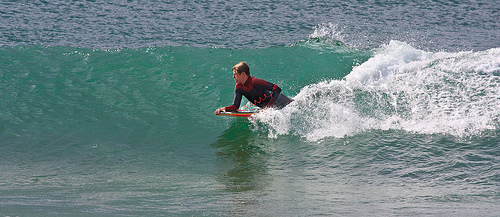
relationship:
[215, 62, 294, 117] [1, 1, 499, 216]
surfer in water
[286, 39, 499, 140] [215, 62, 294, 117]
splashing behind surfer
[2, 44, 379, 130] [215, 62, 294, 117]
wave near surfer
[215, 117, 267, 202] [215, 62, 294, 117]
shadow under surfer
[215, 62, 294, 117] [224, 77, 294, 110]
surfer in suit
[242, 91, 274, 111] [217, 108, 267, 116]
cable on surfboard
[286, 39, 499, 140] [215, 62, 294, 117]
splashing near surfer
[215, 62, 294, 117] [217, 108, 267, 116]
surfer on surfboard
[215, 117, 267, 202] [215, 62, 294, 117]
shadow near surfer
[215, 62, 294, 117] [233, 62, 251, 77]
surfer has wet hair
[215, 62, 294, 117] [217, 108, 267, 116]
surfer with surfboard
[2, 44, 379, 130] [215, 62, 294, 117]
wave behind surfer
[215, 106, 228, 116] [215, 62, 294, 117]
hand of surfer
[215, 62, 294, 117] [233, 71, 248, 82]
surfer side face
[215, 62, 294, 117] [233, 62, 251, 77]
surfer with hair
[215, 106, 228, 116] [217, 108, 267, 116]
hand on surfboard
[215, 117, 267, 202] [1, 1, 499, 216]
shadow in water